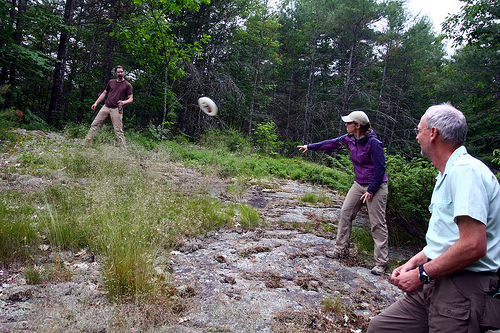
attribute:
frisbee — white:
[194, 75, 227, 122]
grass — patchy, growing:
[92, 192, 143, 275]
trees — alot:
[135, 14, 390, 107]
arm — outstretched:
[127, 75, 138, 115]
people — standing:
[64, 28, 415, 286]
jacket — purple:
[304, 112, 397, 193]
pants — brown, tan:
[299, 184, 402, 272]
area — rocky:
[73, 124, 346, 321]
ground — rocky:
[127, 177, 293, 315]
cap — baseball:
[331, 104, 370, 130]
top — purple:
[315, 134, 398, 188]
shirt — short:
[87, 77, 145, 112]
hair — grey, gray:
[416, 100, 471, 145]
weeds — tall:
[89, 189, 178, 292]